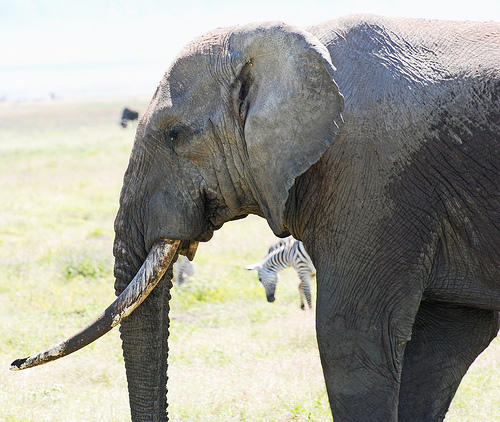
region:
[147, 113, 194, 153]
the eye of an elephant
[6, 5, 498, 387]
a large grey elephant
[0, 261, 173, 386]
the tusk of an elephant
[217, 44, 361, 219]
the ear of an elephant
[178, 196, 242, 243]
the mouth of an elephant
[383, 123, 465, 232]
an elephants wrinkly skin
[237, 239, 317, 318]
a zebra eating some grass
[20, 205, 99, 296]
sparse patches of green grass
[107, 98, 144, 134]
a buffalo in the distance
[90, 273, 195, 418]
the trunk of an elephant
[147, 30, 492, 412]
the elephant is grey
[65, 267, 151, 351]
the tusk has mud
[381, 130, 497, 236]
the skin is wet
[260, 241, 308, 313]
the zebra is black and white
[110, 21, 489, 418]
the elephnat is huge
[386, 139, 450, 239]
wrinkles are on the skin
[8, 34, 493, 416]
the animals are in the wild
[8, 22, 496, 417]
the animals are in africa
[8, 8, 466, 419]
it is sunny in the picture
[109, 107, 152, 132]
animal is in the background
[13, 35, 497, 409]
The elephant is gray.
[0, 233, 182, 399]
His tusks are white.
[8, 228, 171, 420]
His tusk is dirty.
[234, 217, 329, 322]
The zebra is behind the elephant.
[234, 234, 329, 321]
The zebra is white and black.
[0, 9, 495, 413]
The sun is shining.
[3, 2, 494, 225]
The sun is on the elephants back.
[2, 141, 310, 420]
The grass is brown.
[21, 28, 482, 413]
The elephant is standing.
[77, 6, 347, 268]
The elephant has small ears.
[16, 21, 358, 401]
this elephant is old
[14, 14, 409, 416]
elephant in the wild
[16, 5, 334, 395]
the species is african elephant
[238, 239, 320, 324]
a zebra behind elephant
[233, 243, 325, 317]
the zebra is grazing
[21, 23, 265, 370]
the elephant has tusks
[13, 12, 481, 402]
the animals are wild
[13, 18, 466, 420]
a scene from a safari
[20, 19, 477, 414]
the elephant is close up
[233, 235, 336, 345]
the zebra is in the distance